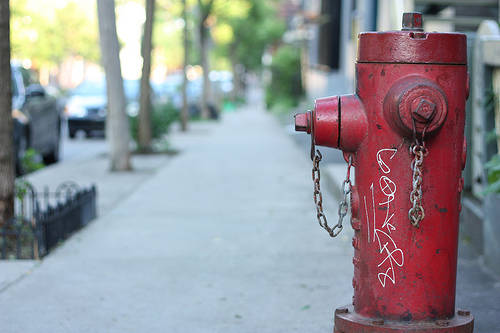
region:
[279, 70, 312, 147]
a long hard nut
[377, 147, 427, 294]
a man written text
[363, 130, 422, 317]
a white text in pillar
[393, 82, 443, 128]
a strong bolt in pillar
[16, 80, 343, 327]
a white clean road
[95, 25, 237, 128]
a group of trees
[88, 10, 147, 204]
a tree in the road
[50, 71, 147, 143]
a car in the road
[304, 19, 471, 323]
red hydrant on sidewalk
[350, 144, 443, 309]
white graffiti on hydrant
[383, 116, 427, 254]
grey chain on hydrant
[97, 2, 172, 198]
tree trunks on sidewalk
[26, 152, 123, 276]
black fence near sidewalk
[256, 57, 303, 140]
green tree behind hydrant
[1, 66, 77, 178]
black truck parked near sidewalk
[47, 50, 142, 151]
black car near sidewalk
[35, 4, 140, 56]
bright sky in distance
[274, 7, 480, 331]
this is a fire hydrant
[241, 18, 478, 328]
the fire hydrant is red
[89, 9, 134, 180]
this is a tree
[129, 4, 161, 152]
this is a tree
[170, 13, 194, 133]
this is a tree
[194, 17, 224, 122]
this is a tree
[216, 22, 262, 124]
this is a tree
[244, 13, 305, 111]
this is a tree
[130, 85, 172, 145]
this is a tree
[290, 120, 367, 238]
this is a chain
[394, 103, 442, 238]
a chain on a fire hydrant.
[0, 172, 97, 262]
A small black metal gate.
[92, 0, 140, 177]
a tall wooden tree.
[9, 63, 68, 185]
A car parked near a parking space.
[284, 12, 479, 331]
A red fire hydrant.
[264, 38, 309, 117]
a large green bush.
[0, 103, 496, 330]
A long sidewalk near a building.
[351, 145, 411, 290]
Graffiti on the side of a fire hydrant.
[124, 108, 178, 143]
a green bush near a car.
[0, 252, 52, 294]
A crack in a sidewalk.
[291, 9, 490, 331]
a red fire hydrant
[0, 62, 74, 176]
a blurry silver car in the background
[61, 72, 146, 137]
a blurry car in the background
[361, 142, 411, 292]
graffiti on a fire hydrant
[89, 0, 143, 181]
a tree sticking out of the sidewalk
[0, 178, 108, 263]
a metal fence on the floor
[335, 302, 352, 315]
a bolt on a fire hydrant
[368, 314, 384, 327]
a bolt on a fire hydrant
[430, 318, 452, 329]
a bolt on a fire hydrant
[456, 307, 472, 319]
a bolt on a fire hydrant